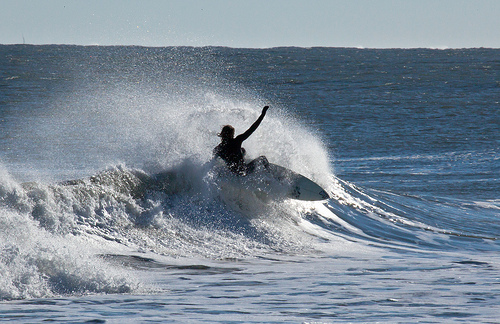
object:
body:
[215, 142, 242, 172]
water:
[0, 48, 500, 324]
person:
[211, 105, 270, 175]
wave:
[54, 182, 200, 257]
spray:
[80, 112, 161, 152]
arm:
[243, 113, 266, 140]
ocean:
[0, 46, 500, 324]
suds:
[190, 184, 245, 243]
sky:
[0, 0, 500, 49]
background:
[0, 0, 500, 110]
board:
[242, 159, 331, 202]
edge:
[291, 25, 461, 103]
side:
[15, 51, 149, 116]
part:
[320, 10, 407, 41]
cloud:
[293, 3, 427, 37]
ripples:
[91, 158, 189, 211]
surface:
[119, 178, 189, 230]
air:
[252, 6, 332, 42]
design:
[292, 185, 301, 199]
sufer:
[200, 126, 290, 174]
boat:
[17, 30, 40, 58]